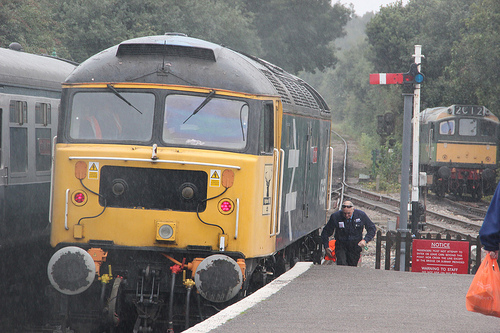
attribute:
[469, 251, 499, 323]
structure — orange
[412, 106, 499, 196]
train — yellow, green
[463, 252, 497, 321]
bag — orange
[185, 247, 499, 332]
platform — loading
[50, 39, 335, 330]
train — closest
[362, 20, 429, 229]
pole — white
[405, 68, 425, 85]
signal lights. — pair, red, green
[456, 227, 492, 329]
bag — orange, plastic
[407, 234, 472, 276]
sign — red, notice, notice warning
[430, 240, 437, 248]
lettering — white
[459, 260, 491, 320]
bag — orange, shopping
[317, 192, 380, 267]
man — walking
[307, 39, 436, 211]
area — large, wooded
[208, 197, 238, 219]
led light — red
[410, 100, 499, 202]
train — yellow, green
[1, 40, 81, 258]
train — green, silver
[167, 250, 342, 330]
line — white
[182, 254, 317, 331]
line — white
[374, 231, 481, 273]
picket fence — brown, wood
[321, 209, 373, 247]
jacket — black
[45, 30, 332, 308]
train — green, yellow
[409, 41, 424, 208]
post — tall, white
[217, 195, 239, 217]
light — led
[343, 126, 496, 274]
tracks — railroad, set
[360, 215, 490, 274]
fence — wooden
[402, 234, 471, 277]
sign — red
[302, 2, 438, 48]
sky — cloudy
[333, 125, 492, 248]
tracks — train